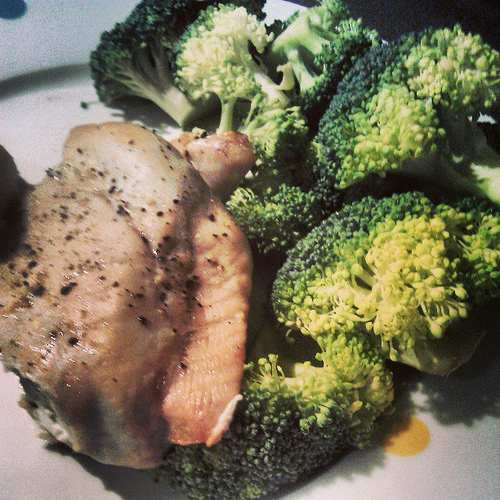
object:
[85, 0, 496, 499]
broccoli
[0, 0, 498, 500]
plate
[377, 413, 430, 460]
grease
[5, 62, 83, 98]
dip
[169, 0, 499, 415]
part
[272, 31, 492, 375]
light green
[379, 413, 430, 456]
dot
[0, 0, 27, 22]
dot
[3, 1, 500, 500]
meal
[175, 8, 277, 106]
piece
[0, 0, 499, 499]
dish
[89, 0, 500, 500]
florets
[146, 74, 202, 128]
stem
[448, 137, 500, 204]
stem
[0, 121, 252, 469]
beef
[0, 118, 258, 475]
pork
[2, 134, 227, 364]
seasoning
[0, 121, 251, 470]
crust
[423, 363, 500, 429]
shadow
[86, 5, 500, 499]
colors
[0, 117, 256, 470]
chicken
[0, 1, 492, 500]
food